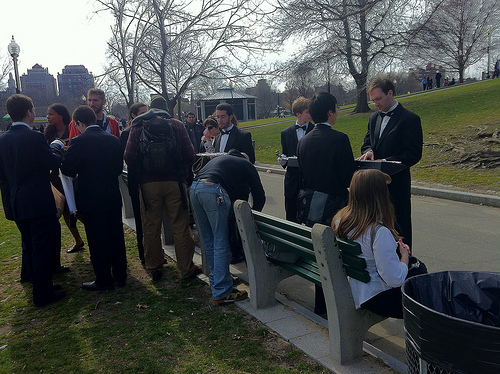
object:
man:
[356, 79, 423, 277]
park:
[7, 63, 494, 373]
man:
[123, 97, 188, 265]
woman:
[329, 168, 406, 314]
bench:
[235, 200, 360, 316]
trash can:
[400, 268, 499, 371]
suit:
[360, 111, 413, 260]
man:
[0, 94, 46, 312]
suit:
[4, 122, 57, 308]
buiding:
[21, 66, 59, 131]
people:
[7, 89, 142, 303]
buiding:
[58, 64, 94, 108]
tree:
[332, 3, 374, 113]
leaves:
[310, 13, 341, 28]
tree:
[112, 0, 180, 114]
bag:
[412, 270, 497, 323]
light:
[7, 33, 23, 139]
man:
[69, 84, 123, 152]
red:
[69, 122, 76, 139]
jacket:
[69, 110, 115, 139]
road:
[412, 159, 498, 267]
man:
[193, 150, 255, 297]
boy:
[282, 100, 316, 217]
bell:
[275, 150, 287, 167]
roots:
[438, 128, 497, 172]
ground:
[329, 79, 499, 189]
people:
[420, 73, 456, 90]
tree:
[425, 2, 490, 84]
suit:
[281, 123, 323, 229]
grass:
[247, 78, 499, 164]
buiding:
[194, 79, 256, 122]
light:
[7, 36, 20, 56]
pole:
[8, 33, 30, 147]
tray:
[357, 158, 402, 167]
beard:
[86, 100, 104, 113]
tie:
[379, 111, 392, 118]